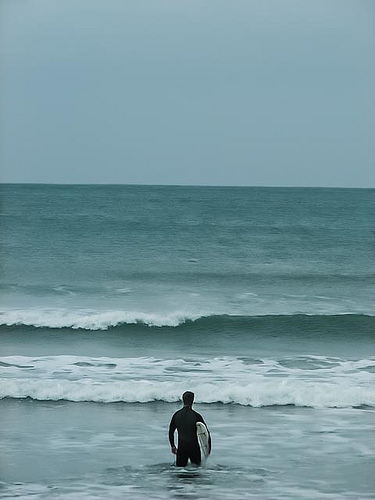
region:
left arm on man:
[161, 422, 177, 460]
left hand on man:
[167, 441, 178, 454]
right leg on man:
[190, 453, 203, 468]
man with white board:
[189, 413, 211, 455]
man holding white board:
[194, 415, 224, 452]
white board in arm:
[188, 415, 223, 464]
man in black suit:
[168, 409, 219, 495]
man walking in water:
[176, 395, 219, 469]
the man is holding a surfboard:
[148, 364, 225, 492]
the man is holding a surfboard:
[147, 377, 221, 474]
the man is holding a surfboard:
[154, 375, 226, 488]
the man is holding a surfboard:
[153, 364, 232, 479]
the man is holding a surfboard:
[153, 370, 216, 478]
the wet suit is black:
[160, 407, 214, 475]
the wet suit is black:
[155, 403, 208, 468]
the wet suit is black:
[166, 402, 207, 459]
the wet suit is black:
[166, 406, 213, 463]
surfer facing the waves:
[155, 362, 227, 486]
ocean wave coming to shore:
[4, 353, 369, 409]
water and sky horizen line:
[1, 167, 373, 203]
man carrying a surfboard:
[165, 384, 218, 471]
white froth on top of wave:
[3, 299, 221, 342]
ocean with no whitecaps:
[3, 177, 373, 290]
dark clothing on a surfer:
[166, 384, 220, 474]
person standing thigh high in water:
[161, 385, 210, 491]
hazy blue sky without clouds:
[4, 4, 370, 194]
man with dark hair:
[165, 385, 215, 475]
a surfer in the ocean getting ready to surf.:
[167, 390, 212, 473]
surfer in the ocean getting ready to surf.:
[168, 386, 213, 467]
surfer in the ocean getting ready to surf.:
[167, 388, 213, 473]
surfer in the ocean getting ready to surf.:
[163, 391, 213, 470]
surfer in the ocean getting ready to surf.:
[168, 392, 213, 469]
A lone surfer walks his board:
[166, 390, 211, 469]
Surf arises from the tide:
[0, 293, 373, 422]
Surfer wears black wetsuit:
[169, 405, 208, 468]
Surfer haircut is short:
[180, 390, 197, 412]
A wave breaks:
[1, 301, 373, 349]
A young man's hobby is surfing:
[168, 389, 214, 474]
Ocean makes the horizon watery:
[1, 167, 374, 205]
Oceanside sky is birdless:
[1, 1, 374, 192]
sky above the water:
[72, 34, 260, 135]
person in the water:
[131, 386, 245, 469]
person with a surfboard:
[125, 383, 242, 488]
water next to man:
[231, 438, 296, 477]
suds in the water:
[242, 421, 332, 475]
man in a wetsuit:
[139, 374, 248, 469]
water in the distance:
[121, 190, 266, 252]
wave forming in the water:
[68, 305, 233, 361]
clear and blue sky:
[65, 20, 313, 126]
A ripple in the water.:
[186, 290, 201, 295]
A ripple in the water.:
[226, 296, 243, 306]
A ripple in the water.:
[107, 283, 135, 301]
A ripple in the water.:
[55, 280, 67, 296]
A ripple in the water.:
[280, 291, 291, 297]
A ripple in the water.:
[239, 354, 278, 369]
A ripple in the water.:
[133, 356, 163, 367]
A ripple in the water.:
[323, 272, 356, 284]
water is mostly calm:
[0, 173, 374, 498]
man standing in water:
[166, 389, 215, 475]